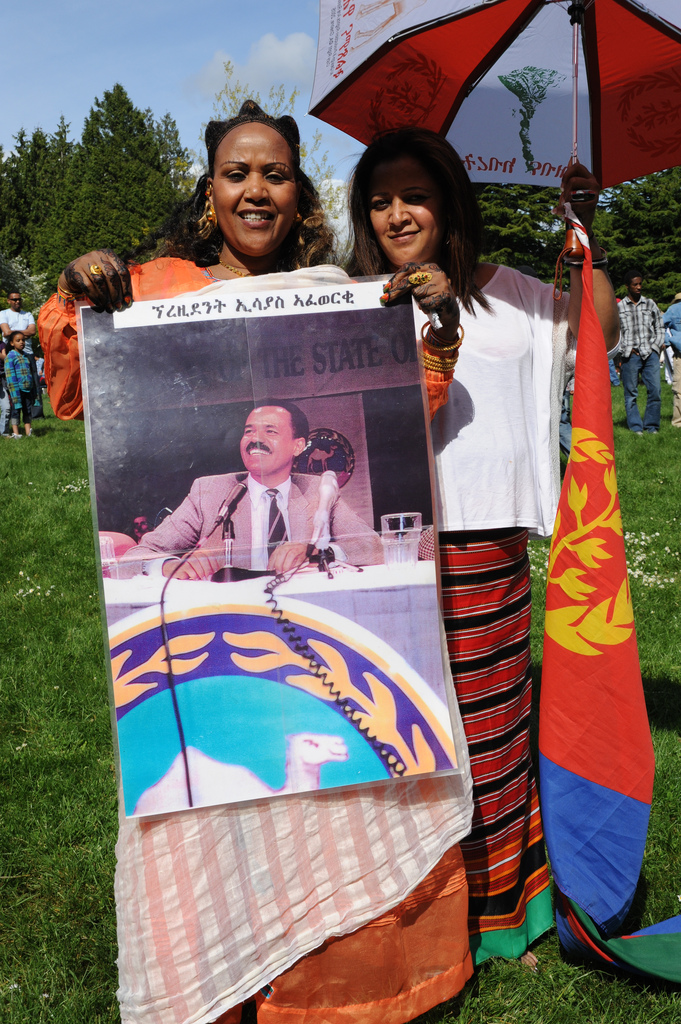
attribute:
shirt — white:
[414, 253, 615, 584]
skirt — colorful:
[404, 494, 555, 905]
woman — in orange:
[117, 95, 299, 971]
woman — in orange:
[86, 121, 365, 948]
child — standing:
[11, 336, 39, 425]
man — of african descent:
[590, 236, 669, 422]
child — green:
[10, 323, 53, 454]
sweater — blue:
[15, 341, 39, 410]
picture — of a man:
[107, 284, 478, 723]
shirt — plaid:
[618, 298, 665, 351]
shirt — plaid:
[614, 292, 668, 391]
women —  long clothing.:
[35, 52, 641, 1006]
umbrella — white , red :
[300, 6, 657, 246]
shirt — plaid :
[618, 297, 658, 356]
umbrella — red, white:
[305, 94, 654, 241]